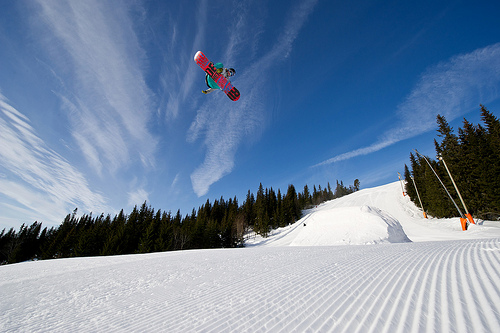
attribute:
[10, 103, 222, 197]
clouds — white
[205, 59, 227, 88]
pants — green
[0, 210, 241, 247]
trees — green